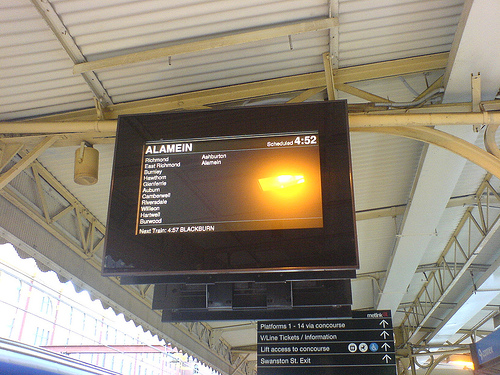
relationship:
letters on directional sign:
[258, 321, 347, 329] [257, 307, 394, 374]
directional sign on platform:
[257, 307, 394, 372] [3, 366, 499, 373]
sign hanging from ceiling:
[153, 280, 353, 324] [3, 1, 497, 372]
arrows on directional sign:
[379, 315, 394, 332] [257, 307, 394, 374]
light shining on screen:
[258, 160, 318, 205] [127, 124, 327, 241]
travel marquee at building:
[102, 98, 362, 280] [1, 0, 499, 373]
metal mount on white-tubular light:
[76, 136, 89, 164] [72, 141, 102, 186]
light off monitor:
[259, 164, 307, 199] [131, 125, 326, 241]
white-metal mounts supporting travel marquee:
[319, 48, 346, 101] [102, 98, 362, 280]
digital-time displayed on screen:
[293, 131, 318, 147] [127, 124, 327, 241]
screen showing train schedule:
[127, 124, 327, 241] [135, 140, 232, 232]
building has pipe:
[1, 0, 499, 370] [350, 104, 499, 129]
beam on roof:
[117, 54, 451, 108] [4, 0, 465, 100]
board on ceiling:
[97, 94, 369, 283] [2, 5, 498, 95]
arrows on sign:
[375, 313, 393, 363] [252, 302, 397, 371]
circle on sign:
[368, 340, 380, 354] [252, 302, 397, 371]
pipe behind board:
[4, 118, 118, 138] [97, 94, 369, 283]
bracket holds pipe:
[92, 98, 113, 116] [59, 89, 184, 112]